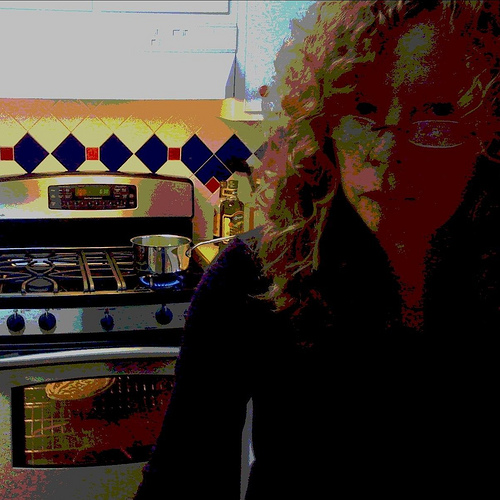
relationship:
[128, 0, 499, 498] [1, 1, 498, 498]
woman in a kitchen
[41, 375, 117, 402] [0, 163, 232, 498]
pizza cooking in an oven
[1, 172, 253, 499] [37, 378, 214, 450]
oven with food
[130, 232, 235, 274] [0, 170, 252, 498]
pot on stove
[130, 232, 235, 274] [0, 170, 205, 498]
pot on stove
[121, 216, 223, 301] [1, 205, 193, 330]
pan on stove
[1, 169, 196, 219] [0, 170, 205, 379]
control panel of oven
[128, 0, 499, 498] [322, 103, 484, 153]
woman wears glasses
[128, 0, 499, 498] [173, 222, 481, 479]
woman wearing top